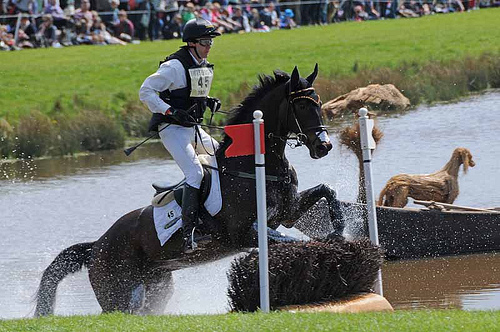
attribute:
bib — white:
[188, 67, 213, 97]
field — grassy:
[0, 13, 497, 135]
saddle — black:
[144, 160, 217, 211]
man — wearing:
[142, 16, 222, 256]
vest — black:
[157, 52, 213, 129]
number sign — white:
[196, 69, 217, 91]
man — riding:
[138, 12, 230, 253]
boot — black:
[171, 230, 216, 256]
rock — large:
[315, 82, 412, 117]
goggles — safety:
[191, 36, 211, 44]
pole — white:
[253, 110, 275, 312]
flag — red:
[220, 106, 312, 325]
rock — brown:
[326, 84, 407, 114]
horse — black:
[31, 62, 333, 312]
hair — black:
[224, 70, 283, 129]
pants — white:
[156, 117, 226, 188]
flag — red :
[193, 90, 292, 190]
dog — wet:
[376, 146, 474, 207]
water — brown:
[0, 63, 494, 319]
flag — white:
[362, 117, 376, 147]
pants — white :
[139, 106, 260, 208]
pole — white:
[250, 108, 270, 317]